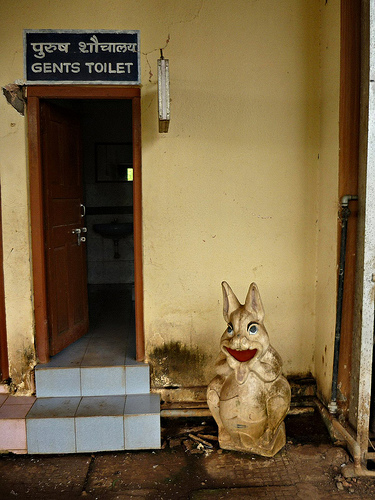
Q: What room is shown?
A: It is a bathroom.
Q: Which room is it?
A: It is a bathroom.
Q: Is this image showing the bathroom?
A: Yes, it is showing the bathroom.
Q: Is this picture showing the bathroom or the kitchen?
A: It is showing the bathroom.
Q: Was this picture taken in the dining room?
A: No, the picture was taken in the bathroom.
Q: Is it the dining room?
A: No, it is the bathroom.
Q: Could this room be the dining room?
A: No, it is the bathroom.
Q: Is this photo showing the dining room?
A: No, the picture is showing the bathroom.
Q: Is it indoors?
A: Yes, it is indoors.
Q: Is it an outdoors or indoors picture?
A: It is indoors.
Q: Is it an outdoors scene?
A: No, it is indoors.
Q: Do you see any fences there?
A: No, there are no fences.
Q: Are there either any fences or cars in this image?
A: No, there are no fences or cars.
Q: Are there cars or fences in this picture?
A: No, there are no fences or cars.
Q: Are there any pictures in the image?
A: No, there are no pictures.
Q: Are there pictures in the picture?
A: No, there are no pictures.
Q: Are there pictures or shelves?
A: No, there are no pictures or shelves.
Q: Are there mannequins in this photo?
A: No, there are no mannequins.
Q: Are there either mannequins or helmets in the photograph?
A: No, there are no mannequins or helmets.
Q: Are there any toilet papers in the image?
A: No, there are no toilet papers.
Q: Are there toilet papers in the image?
A: No, there are no toilet papers.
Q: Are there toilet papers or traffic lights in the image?
A: No, there are no toilet papers or traffic lights.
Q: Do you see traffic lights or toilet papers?
A: No, there are no toilet papers or traffic lights.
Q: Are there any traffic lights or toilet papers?
A: No, there are no toilet papers or traffic lights.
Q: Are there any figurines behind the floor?
A: Yes, there is a figurine behind the floor.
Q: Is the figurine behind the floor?
A: Yes, the figurine is behind the floor.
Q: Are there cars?
A: No, there are no cars.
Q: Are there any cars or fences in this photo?
A: No, there are no cars or fences.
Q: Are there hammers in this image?
A: No, there are no hammers.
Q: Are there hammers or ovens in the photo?
A: No, there are no hammers or ovens.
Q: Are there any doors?
A: Yes, there is a door.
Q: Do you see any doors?
A: Yes, there is a door.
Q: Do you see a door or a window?
A: Yes, there is a door.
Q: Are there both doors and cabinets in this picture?
A: No, there is a door but no cabinets.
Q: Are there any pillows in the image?
A: No, there are no pillows.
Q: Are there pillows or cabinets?
A: No, there are no pillows or cabinets.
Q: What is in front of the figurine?
A: The floor is in front of the figurine.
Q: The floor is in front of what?
A: The floor is in front of the figurine.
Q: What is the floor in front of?
A: The floor is in front of the figurine.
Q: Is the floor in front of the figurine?
A: Yes, the floor is in front of the figurine.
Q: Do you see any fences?
A: No, there are no fences.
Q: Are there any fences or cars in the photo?
A: No, there are no fences or cars.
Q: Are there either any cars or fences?
A: No, there are no fences or cars.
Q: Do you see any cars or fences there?
A: No, there are no fences or cars.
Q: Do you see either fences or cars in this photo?
A: No, there are no fences or cars.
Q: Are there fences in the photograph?
A: No, there are no fences.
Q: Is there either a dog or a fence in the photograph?
A: No, there are no fences or dogs.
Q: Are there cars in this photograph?
A: No, there are no cars.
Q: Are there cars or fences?
A: No, there are no cars or fences.